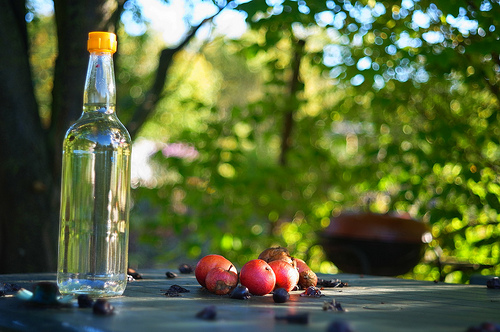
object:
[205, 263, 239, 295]
apple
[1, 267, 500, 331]
table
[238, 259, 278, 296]
apple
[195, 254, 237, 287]
apple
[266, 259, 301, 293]
apple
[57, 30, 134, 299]
bottle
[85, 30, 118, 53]
cap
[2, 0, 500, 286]
tree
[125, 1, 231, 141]
branch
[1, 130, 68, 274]
trunk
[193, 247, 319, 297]
fruit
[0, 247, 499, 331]
berries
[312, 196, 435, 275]
grill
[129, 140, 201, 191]
building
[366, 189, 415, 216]
handle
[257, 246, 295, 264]
apple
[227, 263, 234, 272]
stem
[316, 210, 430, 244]
lid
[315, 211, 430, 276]
bottom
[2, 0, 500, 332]
background